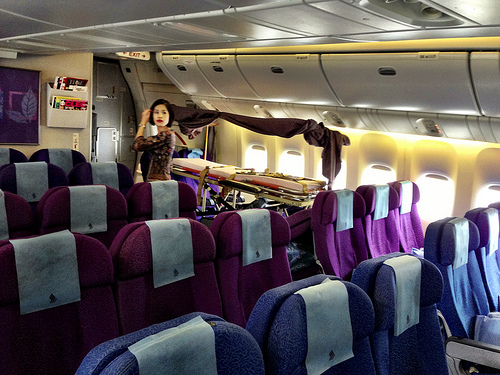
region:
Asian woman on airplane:
[111, 94, 190, 186]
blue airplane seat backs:
[256, 249, 461, 373]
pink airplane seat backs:
[116, 208, 303, 307]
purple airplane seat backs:
[5, 147, 122, 185]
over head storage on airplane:
[168, 42, 388, 119]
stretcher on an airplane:
[176, 146, 318, 217]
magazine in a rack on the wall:
[43, 68, 94, 130]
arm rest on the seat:
[444, 331, 496, 373]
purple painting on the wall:
[6, 63, 47, 148]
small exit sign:
[124, 46, 148, 63]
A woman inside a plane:
[114, 70, 236, 246]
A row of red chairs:
[5, 205, 296, 352]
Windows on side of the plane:
[233, 134, 496, 246]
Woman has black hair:
[137, 92, 177, 140]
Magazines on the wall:
[40, 68, 96, 139]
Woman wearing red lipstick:
[149, 114, 172, 130]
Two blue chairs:
[245, 242, 478, 371]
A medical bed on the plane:
[159, 141, 337, 232]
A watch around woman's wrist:
[130, 118, 151, 134]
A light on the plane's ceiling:
[407, 0, 457, 41]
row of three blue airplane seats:
[86, 257, 443, 374]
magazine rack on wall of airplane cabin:
[45, 74, 95, 161]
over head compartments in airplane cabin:
[153, 41, 498, 130]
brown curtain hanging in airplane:
[153, 100, 353, 183]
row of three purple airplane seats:
[315, 176, 417, 273]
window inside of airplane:
[408, 169, 460, 253]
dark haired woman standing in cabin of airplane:
[123, 73, 186, 183]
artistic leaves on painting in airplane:
[8, 64, 46, 154]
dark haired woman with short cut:
[149, 98, 178, 130]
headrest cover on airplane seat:
[288, 276, 365, 374]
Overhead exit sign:
[116, 46, 153, 65]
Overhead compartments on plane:
[171, 35, 496, 110]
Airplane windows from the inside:
[241, 129, 499, 248]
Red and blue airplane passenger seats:
[0, 207, 416, 367]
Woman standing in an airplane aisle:
[115, 85, 375, 237]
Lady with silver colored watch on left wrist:
[128, 95, 182, 150]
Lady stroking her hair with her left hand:
[136, 95, 181, 128]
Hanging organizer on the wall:
[43, 70, 93, 132]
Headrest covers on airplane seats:
[242, 260, 482, 371]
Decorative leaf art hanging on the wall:
[0, 62, 46, 149]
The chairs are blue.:
[98, 221, 498, 356]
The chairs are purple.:
[5, 178, 433, 276]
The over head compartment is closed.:
[157, 44, 499, 141]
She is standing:
[135, 101, 189, 187]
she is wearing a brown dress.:
[124, 126, 176, 175]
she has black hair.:
[144, 93, 175, 124]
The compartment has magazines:
[41, 72, 93, 154]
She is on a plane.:
[15, 11, 499, 371]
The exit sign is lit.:
[113, 46, 154, 68]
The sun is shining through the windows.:
[242, 141, 497, 245]